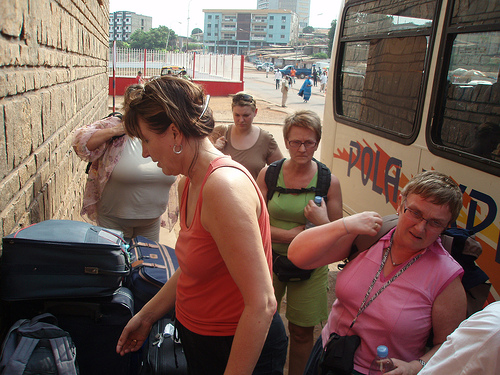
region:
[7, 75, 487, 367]
Bus passengers ready board bus.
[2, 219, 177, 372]
Luggage pile awaits owners.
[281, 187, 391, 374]
Bottled water ready trip.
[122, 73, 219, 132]
Hair clip secures up-do.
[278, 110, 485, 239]
Both women wear eyeglasses.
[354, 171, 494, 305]
Passenger carries large backpack.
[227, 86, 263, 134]
Sunglasses propped top head.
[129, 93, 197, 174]
Pierced earrings ear lobe.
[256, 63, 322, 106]
People walk middle street.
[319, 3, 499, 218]
Vehicle waiting passengers board.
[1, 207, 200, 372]
a pile of luggage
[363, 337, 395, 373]
water bottle with a blue lid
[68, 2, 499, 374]
passengers next to a tour bus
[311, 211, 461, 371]
pink sleeveless shirt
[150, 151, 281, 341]
orange sleeveless tank top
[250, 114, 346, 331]
a woman wearing green shorts and a green tank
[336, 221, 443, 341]
lanyard around a woman's neck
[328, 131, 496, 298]
orange blue and yellow logo on the side of a bus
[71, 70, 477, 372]
women all have short hair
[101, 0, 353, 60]
buildings in the background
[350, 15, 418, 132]
Clear colored bus window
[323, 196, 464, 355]
Older woman wearing pink sleeveless shirt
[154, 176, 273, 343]
Old woman wearing orange tank top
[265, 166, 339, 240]
Old woman wearing green tank top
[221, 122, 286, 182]
Young woman wearing brown shirt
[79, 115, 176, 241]
Woman wearing white shirt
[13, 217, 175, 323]
Blue and brown luggage stacked next to brown brick wall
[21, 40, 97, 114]
Brown brick wall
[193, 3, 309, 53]
White and tan building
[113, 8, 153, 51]
White and tan building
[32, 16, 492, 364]
travelers collect their baggage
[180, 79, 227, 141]
silver clip in the woman's hair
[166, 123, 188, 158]
silver hoop earrings adorn the woman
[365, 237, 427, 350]
black and white lanyard hang from the woman's neck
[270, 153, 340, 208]
black backpack straps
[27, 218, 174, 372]
pile of luggage waits to be collected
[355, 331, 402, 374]
bottle of water with a blue cap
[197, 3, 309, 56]
four-story light blue apartment building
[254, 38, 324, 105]
people walking in the background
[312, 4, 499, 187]
white tourist passenger van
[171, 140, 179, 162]
Woman wearing silver hoop earrings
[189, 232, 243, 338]
Woman wearing red top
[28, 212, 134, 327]
Pile of luggage with blue suitcase on top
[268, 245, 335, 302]
Woman has on black fanny pack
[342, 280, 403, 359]
Woman wearing pink shirt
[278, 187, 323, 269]
Woman wearing green shirt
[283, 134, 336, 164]
Woman is wearing glasses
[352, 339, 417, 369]
Woman holding a bottle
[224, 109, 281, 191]
Woman wearing brown shirt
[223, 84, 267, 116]
Sunglasses on woman's head